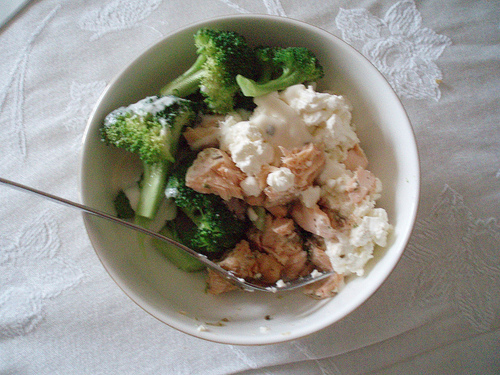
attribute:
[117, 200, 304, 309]
fork — metal, silver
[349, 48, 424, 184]
bowl — round, white, here, wide, close, full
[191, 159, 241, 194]
chicken — orange, brown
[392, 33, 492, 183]
table — white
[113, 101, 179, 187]
broccoli — close, small, green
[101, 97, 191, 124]
dressing — ranch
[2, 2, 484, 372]
linen — white